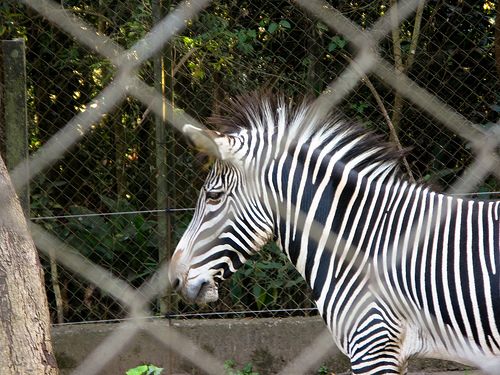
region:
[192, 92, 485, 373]
this is a zebra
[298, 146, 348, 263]
the zebra has white and black strips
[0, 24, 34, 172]
this is a pole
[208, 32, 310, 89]
this is a tree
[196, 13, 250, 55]
the leaves are green in color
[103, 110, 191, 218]
this is the fence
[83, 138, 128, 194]
this is a wiremesh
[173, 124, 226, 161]
this is the ear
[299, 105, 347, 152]
this is the fur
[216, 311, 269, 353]
this is a wall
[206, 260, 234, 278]
black stripe on zebra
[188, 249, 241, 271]
black stripe on zebra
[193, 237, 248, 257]
black stripe on zebra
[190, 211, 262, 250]
black stripe on zebra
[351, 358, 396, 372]
black stripe on zebra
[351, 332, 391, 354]
black stripe on zebra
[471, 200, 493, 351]
black stripe on zebra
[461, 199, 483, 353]
black stripe on zebra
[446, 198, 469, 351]
black stripe on zebra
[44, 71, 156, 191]
A fence in the background.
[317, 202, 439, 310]
The zebra's striped exterior.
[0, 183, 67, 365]
A tree trunk.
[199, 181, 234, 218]
The zebra's black eye.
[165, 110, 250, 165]
The zebra's ear.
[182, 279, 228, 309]
The zebra's mouth.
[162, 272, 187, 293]
The zebra's nose.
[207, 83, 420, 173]
The zebra's black and white hair.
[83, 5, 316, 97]
The trees in the background.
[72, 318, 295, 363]
The cemented wall in the background.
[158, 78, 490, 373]
This is a zebra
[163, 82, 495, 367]
This is a zebra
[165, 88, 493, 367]
This is a zebra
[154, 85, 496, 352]
This is a zebra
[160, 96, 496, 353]
This is a zebra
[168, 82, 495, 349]
This is a zebra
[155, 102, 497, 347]
This is a zebra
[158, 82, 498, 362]
This is a zebra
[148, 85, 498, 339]
This is a zebra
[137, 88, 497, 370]
This is a zebra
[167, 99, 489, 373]
a zebra in a cage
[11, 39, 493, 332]
a chain link fence around the zebra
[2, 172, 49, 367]
the trunk of a tree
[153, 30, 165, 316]
a metal pole on the fence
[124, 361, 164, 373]
leaves next to the zebra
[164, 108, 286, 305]
the head of the zebra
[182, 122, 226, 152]
the ear of the zebra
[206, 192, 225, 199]
the eye of the zebra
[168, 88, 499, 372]
a black and white zebra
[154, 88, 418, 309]
mane of zebra standing up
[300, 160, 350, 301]
black and white stripe on zebra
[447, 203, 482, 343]
black and white stripe on zebra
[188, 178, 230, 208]
zebra has eye on side of head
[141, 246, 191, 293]
zebra has nose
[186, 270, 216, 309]
zebra has mouth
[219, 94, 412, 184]
zebra has a main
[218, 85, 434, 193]
the main is black and white in color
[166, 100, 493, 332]
the zebra has stripes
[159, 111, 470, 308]
stripes are black and white in color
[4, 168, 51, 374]
trunk of the tree is brown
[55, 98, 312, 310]
leaves of the bush are green